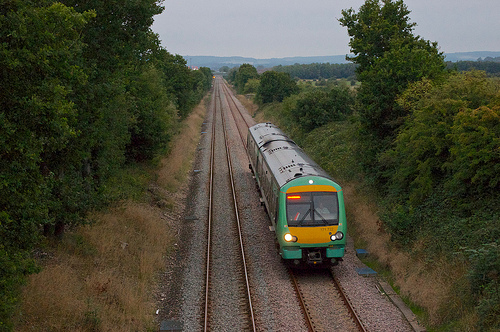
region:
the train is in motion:
[240, 118, 340, 266]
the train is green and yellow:
[248, 117, 348, 273]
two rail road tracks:
[202, 80, 246, 130]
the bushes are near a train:
[249, 4, 497, 271]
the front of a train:
[284, 176, 346, 267]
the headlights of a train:
[280, 230, 346, 242]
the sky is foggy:
[187, 2, 345, 64]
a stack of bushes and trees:
[1, 0, 211, 324]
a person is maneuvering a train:
[286, 192, 336, 226]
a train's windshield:
[286, 190, 338, 222]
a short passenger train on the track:
[243, 118, 346, 268]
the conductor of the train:
[313, 199, 329, 221]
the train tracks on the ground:
[211, 78, 361, 330]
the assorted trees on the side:
[226, 58, 498, 263]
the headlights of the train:
[276, 227, 343, 243]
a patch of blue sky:
[162, 7, 348, 69]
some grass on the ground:
[14, 200, 160, 330]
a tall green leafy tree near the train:
[338, 10, 442, 92]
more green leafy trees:
[275, 58, 353, 79]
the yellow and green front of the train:
[278, 174, 353, 259]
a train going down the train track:
[5, 2, 495, 322]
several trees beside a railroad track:
[5, 0, 240, 325]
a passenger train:
[235, 115, 360, 280]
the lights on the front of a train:
[280, 220, 345, 251]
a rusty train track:
[187, 102, 263, 329]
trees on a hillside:
[246, 50, 498, 138]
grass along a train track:
[91, 149, 236, 309]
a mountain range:
[176, 43, 498, 79]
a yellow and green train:
[236, 113, 364, 271]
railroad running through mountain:
[26, 19, 457, 319]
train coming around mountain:
[77, 39, 439, 308]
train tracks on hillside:
[97, 32, 369, 313]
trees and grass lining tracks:
[10, 17, 205, 316]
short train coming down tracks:
[241, 113, 360, 296]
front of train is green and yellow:
[275, 172, 362, 262]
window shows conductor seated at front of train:
[275, 175, 358, 260]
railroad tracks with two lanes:
[200, 63, 332, 325]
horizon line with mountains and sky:
[182, 24, 329, 95]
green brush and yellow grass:
[86, 58, 193, 329]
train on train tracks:
[234, 85, 342, 330]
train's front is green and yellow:
[248, 149, 367, 314]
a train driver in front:
[293, 185, 343, 229]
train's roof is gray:
[229, 84, 326, 214]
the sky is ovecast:
[182, 15, 329, 60]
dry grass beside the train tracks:
[325, 165, 460, 327]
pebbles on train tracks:
[200, 162, 276, 310]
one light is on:
[275, 221, 313, 253]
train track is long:
[191, 70, 307, 330]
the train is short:
[248, 113, 379, 330]